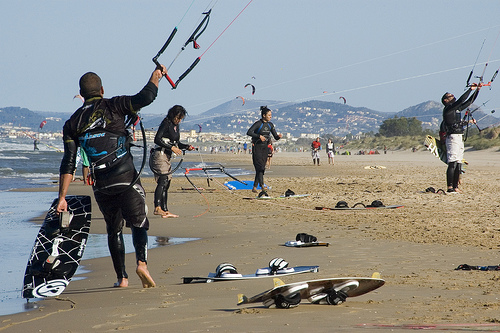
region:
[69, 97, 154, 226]
peson wearing black wet suit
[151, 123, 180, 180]
peson wearing black wet suit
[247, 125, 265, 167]
peson wearing black wet suit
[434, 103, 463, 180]
peson wearing black wet suit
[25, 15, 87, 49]
blue sky with out clouds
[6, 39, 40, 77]
blue sky with out clouds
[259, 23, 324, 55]
blue sky with out clouds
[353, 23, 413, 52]
blue sky with out clouds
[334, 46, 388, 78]
blue sky with out clouds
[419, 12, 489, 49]
blue sky with out clouds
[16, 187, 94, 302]
A man holding a surfboard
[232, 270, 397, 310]
A surfboard facing down in the sand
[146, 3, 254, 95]
A man holding his kite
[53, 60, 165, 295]
A man has a wet suit and surfer shorts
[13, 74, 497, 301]
Several people flying their kites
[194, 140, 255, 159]
A group of people on the beach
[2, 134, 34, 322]
The water washing up on the beach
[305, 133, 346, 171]
A couple walking together on the beach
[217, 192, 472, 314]
The sand on the beach is muddy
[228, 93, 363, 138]
The houses on the mountain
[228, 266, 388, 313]
a surfboard on the beach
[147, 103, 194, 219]
a woman fixing a harness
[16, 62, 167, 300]
a man in a wetsuit holding a surfboard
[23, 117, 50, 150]
person in the backgroung sailing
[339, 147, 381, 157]
sunbathers on the beach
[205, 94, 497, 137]
mountains in the background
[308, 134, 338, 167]
couple walking on the beach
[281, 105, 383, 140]
houses on the hill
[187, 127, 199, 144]
lifegaurd stand on the beach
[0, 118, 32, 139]
pier on the beach near the water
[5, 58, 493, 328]
People on the beach.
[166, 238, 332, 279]
A board on the beach.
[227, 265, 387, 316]
An upside down board on the beach.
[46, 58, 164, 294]
The man is wearing a wet suit.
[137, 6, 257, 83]
The man is holding a kite by the strings.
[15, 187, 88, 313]
The man is dragging a black and white board.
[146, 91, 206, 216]
The woman is wearing a wet suit.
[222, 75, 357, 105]
Kites in the air.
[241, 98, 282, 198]
Another woman is wearing a wet suit.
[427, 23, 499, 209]
Another man is holding on to the strings of a kite.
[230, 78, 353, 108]
kites in the sky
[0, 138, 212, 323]
blue water at the beach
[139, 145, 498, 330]
sand at the beach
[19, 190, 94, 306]
black and white wake board in the man's hand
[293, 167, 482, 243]
footprints in the sand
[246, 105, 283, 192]
woman with hair up and wearing a black and blue wetsuit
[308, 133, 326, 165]
person wearing a red top and white bottoms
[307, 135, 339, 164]
a couple walking along the beach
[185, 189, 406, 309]
boards in the sand